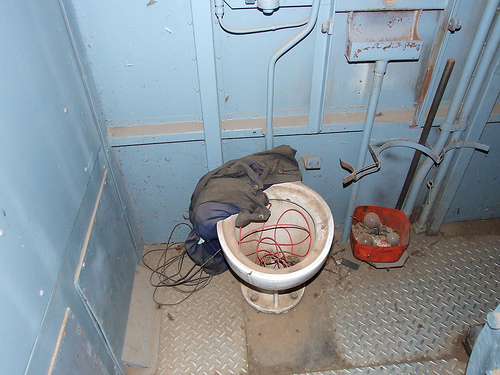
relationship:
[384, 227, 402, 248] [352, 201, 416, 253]
bulb inside bucket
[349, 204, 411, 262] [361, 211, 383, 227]
container full of bulbs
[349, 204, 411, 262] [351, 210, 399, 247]
container full of junk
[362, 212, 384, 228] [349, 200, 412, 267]
light bulb in red bucket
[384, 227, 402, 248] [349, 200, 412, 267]
bulb in red bucket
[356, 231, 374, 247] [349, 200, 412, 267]
bulb in red bucket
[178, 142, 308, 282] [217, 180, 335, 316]
clothing on toilet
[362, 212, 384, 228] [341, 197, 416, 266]
light bulb in bucket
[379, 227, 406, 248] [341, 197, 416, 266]
bulb in bucket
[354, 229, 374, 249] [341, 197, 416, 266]
bulb in bucket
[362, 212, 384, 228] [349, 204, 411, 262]
light bulb in container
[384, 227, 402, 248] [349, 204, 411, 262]
bulb in container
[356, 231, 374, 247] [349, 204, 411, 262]
bulb in container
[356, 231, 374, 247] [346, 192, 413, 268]
bulb in bucket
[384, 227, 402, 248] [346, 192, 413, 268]
bulb in bucket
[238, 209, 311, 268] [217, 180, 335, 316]
wires in toilet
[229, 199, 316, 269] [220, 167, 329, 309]
wires in bucket